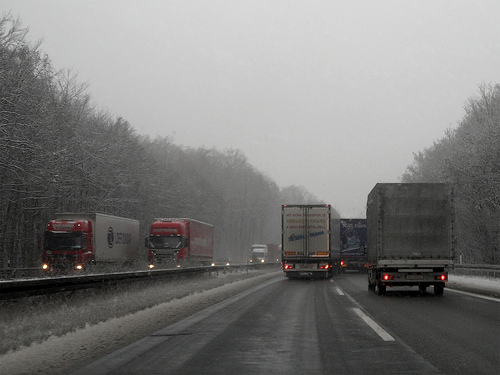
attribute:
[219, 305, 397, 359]
road — black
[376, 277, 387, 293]
tire — black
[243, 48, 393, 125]
sky — dull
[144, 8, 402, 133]
sky — gray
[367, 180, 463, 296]
truck — dirty, white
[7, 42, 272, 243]
trees — snow, covered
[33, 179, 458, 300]
trucks — several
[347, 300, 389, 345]
lines — WHITE